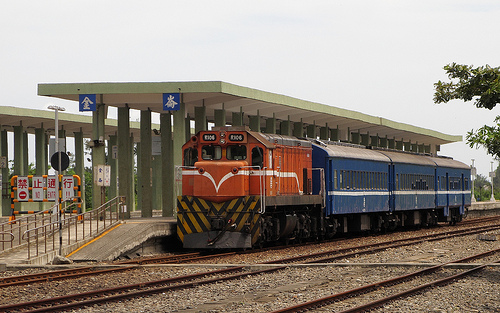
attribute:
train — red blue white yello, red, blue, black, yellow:
[179, 130, 473, 248]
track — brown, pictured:
[3, 215, 497, 286]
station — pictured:
[38, 80, 464, 269]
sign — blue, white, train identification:
[162, 89, 181, 110]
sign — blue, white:
[75, 94, 98, 111]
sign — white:
[94, 161, 115, 188]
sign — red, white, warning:
[8, 173, 83, 205]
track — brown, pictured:
[7, 223, 499, 313]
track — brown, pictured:
[268, 248, 498, 311]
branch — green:
[436, 63, 498, 110]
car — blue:
[305, 138, 390, 216]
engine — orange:
[180, 131, 311, 214]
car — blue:
[376, 146, 434, 214]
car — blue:
[425, 153, 468, 205]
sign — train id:
[202, 133, 219, 141]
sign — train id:
[229, 134, 247, 141]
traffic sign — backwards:
[49, 151, 70, 173]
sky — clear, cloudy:
[0, 1, 499, 189]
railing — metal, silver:
[18, 196, 117, 258]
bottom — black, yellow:
[177, 196, 475, 231]